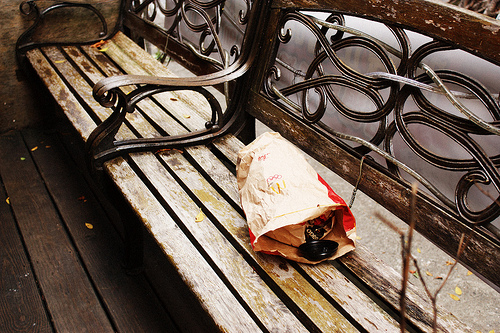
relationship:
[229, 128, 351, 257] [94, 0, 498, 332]
bag on bench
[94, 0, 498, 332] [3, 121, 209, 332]
bench on porch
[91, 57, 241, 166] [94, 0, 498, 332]
arm on bench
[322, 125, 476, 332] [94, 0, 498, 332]
twigs near bench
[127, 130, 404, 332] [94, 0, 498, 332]
slats in bench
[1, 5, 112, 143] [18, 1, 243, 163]
wall at end of bench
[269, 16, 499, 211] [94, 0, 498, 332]
lighting interwound on bench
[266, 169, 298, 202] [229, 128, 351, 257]
logo on bag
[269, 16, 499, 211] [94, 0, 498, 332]
lighting woven through bench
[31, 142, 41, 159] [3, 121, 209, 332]
cigarette butt on porch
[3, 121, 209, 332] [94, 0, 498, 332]
porch under bench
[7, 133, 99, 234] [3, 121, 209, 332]
leaves on porch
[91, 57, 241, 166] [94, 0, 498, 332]
arm of bench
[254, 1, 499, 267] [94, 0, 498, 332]
back of bench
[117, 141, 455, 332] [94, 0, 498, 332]
seat of bench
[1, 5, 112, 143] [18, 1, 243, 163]
wall next to bench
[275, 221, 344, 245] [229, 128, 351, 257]
wrapper in bag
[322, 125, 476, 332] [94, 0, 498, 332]
twigs in front of bench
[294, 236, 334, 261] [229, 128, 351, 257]
coffee lid in bag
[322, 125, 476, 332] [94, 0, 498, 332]
twigs next to bench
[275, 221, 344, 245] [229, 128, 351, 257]
wrapper inside of bag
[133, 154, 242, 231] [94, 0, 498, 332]
scratches on bench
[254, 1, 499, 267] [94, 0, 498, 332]
back on bench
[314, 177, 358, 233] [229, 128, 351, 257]
sign on bag